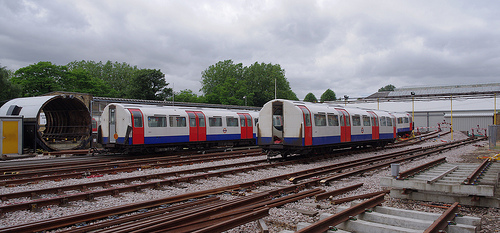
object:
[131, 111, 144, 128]
window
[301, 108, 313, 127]
window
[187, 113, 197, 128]
window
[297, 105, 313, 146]
car door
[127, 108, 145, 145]
car door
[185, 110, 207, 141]
car door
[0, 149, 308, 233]
railroad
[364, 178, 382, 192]
gravel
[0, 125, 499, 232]
train tracks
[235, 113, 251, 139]
doors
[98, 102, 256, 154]
train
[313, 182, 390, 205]
rails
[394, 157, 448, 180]
rails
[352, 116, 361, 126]
window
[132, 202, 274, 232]
metal rails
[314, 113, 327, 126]
window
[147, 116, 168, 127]
window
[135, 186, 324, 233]
tracks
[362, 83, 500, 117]
buildings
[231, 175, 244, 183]
gravel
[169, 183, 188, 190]
wood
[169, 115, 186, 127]
window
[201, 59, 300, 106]
trees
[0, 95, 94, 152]
culvert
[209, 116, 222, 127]
window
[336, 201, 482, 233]
cement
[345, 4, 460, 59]
clouds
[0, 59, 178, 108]
trees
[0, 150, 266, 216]
track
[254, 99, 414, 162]
cars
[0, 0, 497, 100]
sky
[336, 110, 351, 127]
windows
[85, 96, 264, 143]
station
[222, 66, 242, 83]
leaves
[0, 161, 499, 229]
ground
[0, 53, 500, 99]
background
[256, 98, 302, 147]
back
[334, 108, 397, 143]
doors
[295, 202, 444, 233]
railroad ties